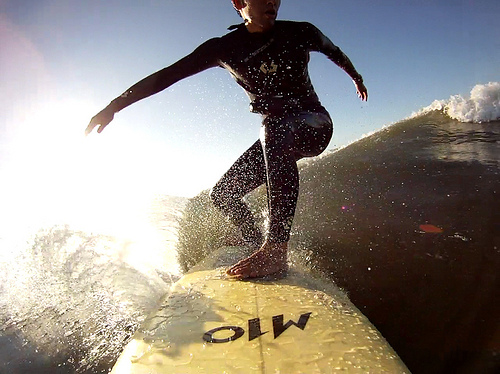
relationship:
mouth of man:
[262, 7, 278, 19] [76, 3, 380, 285]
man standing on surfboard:
[76, 3, 380, 285] [106, 202, 406, 372]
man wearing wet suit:
[76, 3, 380, 285] [112, 20, 361, 242]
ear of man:
[231, 1, 246, 12] [76, 3, 380, 285]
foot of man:
[225, 236, 286, 285] [76, 3, 380, 285]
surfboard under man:
[106, 202, 406, 372] [76, 3, 380, 285]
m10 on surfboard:
[199, 306, 310, 349] [106, 202, 406, 372]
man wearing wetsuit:
[76, 3, 380, 285] [113, 20, 364, 243]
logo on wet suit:
[235, 42, 303, 85] [112, 20, 361, 242]